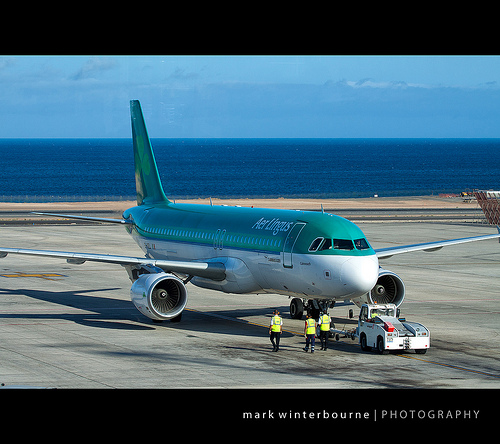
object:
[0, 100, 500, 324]
plane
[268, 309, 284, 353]
man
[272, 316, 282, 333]
yellow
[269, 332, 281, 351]
jeans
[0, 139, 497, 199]
water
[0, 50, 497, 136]
sky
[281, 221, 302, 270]
door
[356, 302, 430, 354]
carrier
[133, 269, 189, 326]
fan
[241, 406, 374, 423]
person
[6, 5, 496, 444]
picture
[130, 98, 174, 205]
tail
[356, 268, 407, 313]
left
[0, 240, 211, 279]
wing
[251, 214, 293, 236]
white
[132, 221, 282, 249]
windows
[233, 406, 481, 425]
picture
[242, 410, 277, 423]
mark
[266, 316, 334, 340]
controlling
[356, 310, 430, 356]
luggage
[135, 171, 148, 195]
clover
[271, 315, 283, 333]
orange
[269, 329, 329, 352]
walking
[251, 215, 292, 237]
name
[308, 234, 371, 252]
windows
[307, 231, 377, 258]
cockpit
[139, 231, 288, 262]
stripe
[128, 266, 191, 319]
engines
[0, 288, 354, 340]
shadow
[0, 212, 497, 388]
runway